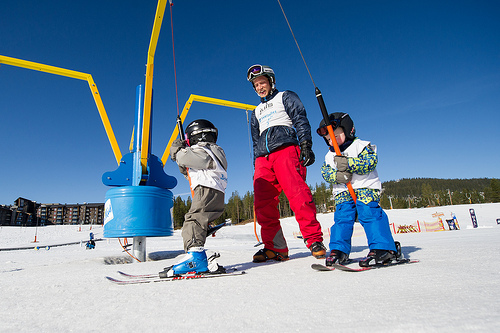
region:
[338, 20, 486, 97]
The sky is clear and blue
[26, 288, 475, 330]
The snow is the color white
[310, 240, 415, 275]
The boy is wearing skis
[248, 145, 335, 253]
The man is wearing red pants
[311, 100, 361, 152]
The kid has on a helmet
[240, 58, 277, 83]
The man is wearing snow goggles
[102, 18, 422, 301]
The boys are on a snow ride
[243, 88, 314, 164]
The man is wearing a dark blue jacket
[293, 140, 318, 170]
The man is wearing a black glove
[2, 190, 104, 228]
The hotel is the color brown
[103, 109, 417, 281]
two small children skiing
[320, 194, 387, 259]
blue pants of child skiing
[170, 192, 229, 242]
gray pants of child skiing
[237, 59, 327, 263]
ski instructor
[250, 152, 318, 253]
red pants of ski instructor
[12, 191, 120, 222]
building on mountain top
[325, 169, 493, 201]
tree covered mountain in background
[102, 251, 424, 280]
skis of two children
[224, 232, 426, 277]
shadows of skiers on snow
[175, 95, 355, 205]
orange and black poles children are holding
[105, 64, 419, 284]
family is skiing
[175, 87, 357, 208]
two children holding black and orange handles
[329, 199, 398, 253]
child wearing blue snow pants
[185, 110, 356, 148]
children wearing black helmets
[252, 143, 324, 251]
man wearing pink snow pants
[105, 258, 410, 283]
children wearing small skiis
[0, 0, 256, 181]
yellow poles are sticking out of base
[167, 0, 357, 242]
wires extend from poles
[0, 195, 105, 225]
building behind poles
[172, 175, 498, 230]
trees behind family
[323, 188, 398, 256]
The boy has on blue pants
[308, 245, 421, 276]
The boy is wearing snow skis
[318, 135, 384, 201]
The boy is wearing a jacket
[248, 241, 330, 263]
The man is wearing yellow shoes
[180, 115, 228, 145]
The boy is wearing a helmet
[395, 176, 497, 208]
The mountains in the back of the slopes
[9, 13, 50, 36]
white clouds in blue sky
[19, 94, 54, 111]
white clouds in blue sky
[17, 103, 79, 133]
white clouds in blue sky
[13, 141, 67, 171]
white clouds in blue sky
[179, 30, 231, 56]
white clouds in blue sky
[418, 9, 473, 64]
white clouds in blue sky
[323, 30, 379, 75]
white clouds in blue sky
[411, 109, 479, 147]
white clouds in blue sky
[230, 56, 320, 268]
skier in white snow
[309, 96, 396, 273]
shier in white snow